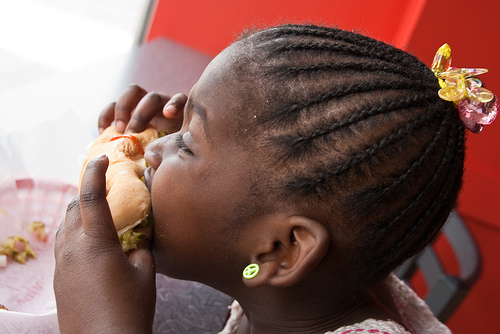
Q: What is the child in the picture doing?
A: Eating.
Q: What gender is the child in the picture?
A: Female.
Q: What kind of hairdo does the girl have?
A: Cornrolls.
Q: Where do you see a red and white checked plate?
A: On the table.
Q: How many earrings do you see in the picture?
A: One.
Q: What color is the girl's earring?
A: Yellow.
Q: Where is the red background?
A: Behind the girl.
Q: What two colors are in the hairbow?
A: Yellow and pink.